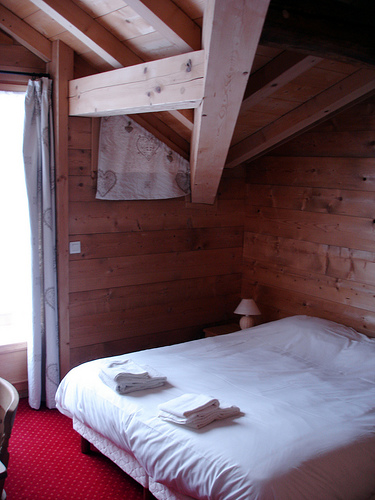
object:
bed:
[55, 314, 374, 499]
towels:
[100, 361, 149, 382]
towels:
[158, 392, 220, 419]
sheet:
[55, 314, 374, 499]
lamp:
[233, 298, 260, 331]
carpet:
[3, 398, 153, 498]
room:
[0, 1, 373, 499]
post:
[80, 436, 90, 455]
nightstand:
[203, 323, 244, 337]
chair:
[0, 376, 19, 499]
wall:
[64, 115, 244, 374]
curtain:
[95, 115, 193, 201]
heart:
[96, 168, 117, 197]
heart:
[136, 136, 160, 161]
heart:
[175, 171, 191, 193]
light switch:
[69, 240, 81, 255]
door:
[0, 72, 59, 403]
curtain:
[23, 78, 58, 413]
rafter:
[64, 49, 202, 118]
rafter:
[79, 0, 197, 60]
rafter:
[231, 55, 355, 145]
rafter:
[189, 0, 270, 206]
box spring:
[71, 416, 148, 489]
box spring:
[149, 482, 181, 500]